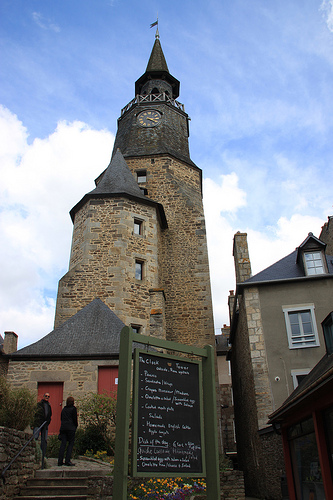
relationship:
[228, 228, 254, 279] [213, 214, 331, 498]
chimney on building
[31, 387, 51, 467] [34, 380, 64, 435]
man in front of door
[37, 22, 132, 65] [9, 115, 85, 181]
blue sky with clouds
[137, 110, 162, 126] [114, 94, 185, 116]
clock in terrace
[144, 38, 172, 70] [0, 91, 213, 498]
roof in building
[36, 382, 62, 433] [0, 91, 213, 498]
door in building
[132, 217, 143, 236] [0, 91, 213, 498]
window in building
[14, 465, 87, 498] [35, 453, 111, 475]
steps in landing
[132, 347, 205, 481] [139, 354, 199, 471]
frame in blackboard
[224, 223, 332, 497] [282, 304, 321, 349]
building with window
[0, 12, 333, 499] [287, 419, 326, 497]
building with window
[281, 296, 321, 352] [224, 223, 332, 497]
window on a building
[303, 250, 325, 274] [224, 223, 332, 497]
window on a building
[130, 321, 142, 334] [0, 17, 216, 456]
window on a building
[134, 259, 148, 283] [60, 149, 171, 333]
window on a building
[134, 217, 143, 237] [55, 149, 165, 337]
window on a building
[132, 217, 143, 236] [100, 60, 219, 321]
window on a building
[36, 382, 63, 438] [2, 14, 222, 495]
door on a building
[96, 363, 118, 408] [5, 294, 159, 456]
door on a building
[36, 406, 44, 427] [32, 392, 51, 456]
arm of a man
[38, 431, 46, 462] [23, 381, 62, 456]
leg of a man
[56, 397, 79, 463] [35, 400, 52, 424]
man wearing a shirt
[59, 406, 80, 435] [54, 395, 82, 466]
back of a woman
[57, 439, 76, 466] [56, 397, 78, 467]
legs of a man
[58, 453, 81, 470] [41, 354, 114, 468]
feet of a woman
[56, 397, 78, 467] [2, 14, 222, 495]
man near a building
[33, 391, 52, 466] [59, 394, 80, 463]
man and woman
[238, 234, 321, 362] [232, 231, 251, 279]
house with chimney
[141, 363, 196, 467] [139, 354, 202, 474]
writing on blackboard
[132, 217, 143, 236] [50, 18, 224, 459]
window in clock tower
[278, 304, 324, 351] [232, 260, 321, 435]
window on building